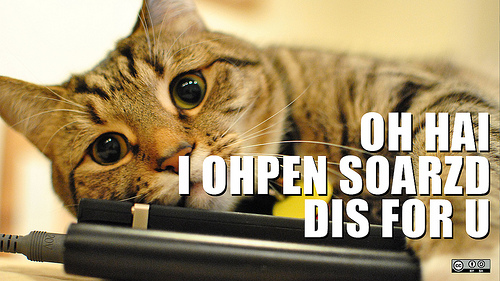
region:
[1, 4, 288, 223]
the head of a cat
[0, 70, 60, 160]
the ear of a cat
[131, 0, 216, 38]
the ear of a cat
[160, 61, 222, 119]
the eye of a cat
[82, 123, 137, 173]
the eye of a cat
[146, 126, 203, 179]
the nose of a cat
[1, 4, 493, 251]
a cat laying on a laptop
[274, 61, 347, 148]
the fur of a cat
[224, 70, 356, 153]
the whiskers of a cat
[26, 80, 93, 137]
the eye lashes of a cat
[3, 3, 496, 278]
A cat meme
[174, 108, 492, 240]
Lol cat speak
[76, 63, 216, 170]
The eyes of a cat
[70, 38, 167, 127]
An M pattern on a cat's head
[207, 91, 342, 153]
The whiskers of a cat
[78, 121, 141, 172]
The right eye of a cat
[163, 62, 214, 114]
The left eye of a cat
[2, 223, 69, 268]
An electrical charger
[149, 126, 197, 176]
The nose of a cat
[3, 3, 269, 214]
The head of a cat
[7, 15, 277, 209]
head of a cat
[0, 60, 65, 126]
ear of a cat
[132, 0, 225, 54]
ear of a cat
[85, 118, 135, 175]
eye of a cat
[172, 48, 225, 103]
eye of a cat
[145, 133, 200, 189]
nose of a cat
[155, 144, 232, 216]
mouth of a cat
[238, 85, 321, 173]
whisker of a cat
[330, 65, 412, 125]
fur of a cat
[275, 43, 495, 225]
body of a cat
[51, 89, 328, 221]
the cat has whiskers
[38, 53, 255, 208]
cat's eyes are black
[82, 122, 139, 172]
right eye on cat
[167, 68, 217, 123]
left eye on cat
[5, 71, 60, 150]
right ear on cat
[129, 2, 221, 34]
left ear on cat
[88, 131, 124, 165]
black pupil in eye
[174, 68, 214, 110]
black pupil in eye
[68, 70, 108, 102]
black fur on cat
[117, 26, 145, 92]
black fur on cat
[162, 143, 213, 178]
small nose on cat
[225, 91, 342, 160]
white whiskers on cat